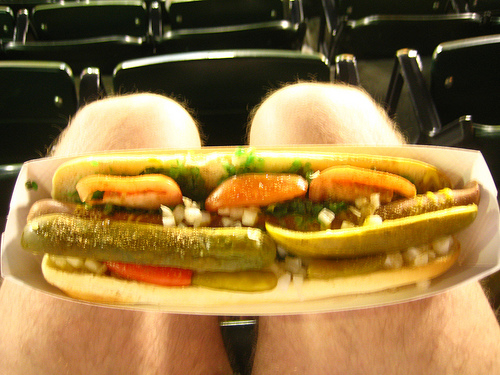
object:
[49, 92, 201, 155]
knee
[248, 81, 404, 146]
knee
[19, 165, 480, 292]
toppings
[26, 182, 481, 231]
hotdog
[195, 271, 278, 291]
pepper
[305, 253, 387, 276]
pepper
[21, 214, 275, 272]
pickle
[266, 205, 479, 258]
pickle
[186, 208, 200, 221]
onion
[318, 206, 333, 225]
onion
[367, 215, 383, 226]
onion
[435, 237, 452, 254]
onion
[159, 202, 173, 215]
onion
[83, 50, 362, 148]
chair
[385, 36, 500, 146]
chair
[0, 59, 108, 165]
chair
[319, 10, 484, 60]
chair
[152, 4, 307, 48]
chair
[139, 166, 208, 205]
relish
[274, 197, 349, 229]
relish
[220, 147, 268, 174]
relish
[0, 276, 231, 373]
leg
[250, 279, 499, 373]
leg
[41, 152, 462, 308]
hotdog bun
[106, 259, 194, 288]
pepper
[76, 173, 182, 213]
tomato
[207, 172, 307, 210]
tomato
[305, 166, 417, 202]
tomato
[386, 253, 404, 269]
onion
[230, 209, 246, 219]
onion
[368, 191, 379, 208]
onion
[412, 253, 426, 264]
onion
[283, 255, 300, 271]
onion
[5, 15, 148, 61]
chair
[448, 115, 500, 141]
top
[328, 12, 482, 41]
top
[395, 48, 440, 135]
armrest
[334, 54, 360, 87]
armrest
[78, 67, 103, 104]
armrest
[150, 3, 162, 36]
armrest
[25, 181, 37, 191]
relish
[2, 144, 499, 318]
box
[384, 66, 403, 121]
leg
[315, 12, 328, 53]
leg